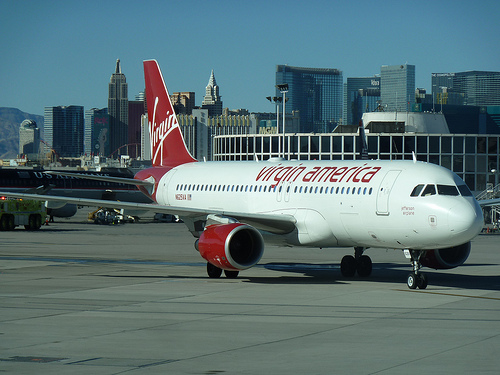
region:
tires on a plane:
[404, 266, 434, 293]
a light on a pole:
[273, 74, 303, 134]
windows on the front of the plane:
[413, 181, 446, 198]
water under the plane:
[271, 250, 317, 275]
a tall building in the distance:
[200, 65, 226, 116]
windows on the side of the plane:
[176, 175, 229, 193]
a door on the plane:
[375, 162, 397, 222]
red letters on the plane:
[258, 157, 309, 187]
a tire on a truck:
[23, 207, 48, 232]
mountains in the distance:
[3, 100, 26, 131]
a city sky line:
[17, 60, 490, 167]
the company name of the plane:
[249, 160, 379, 190]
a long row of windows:
[168, 181, 372, 205]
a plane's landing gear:
[334, 250, 377, 280]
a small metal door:
[375, 167, 398, 217]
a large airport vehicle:
[3, 195, 49, 232]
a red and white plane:
[18, 59, 485, 293]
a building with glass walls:
[209, 128, 491, 194]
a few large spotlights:
[261, 83, 293, 135]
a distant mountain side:
[0, 98, 55, 160]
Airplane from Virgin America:
[4, 55, 489, 305]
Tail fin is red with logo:
[116, 37, 200, 210]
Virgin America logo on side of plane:
[244, 150, 389, 195]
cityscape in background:
[1, 53, 495, 193]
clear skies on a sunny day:
[5, 3, 497, 103]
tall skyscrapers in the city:
[2, 47, 493, 148]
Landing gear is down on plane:
[190, 210, 455, 310]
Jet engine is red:
[192, 212, 265, 285]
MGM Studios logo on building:
[243, 110, 293, 150]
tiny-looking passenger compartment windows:
[172, 174, 379, 202]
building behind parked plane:
[108, 58, 128, 165]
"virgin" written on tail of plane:
[145, 96, 179, 163]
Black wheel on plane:
[206, 258, 223, 278]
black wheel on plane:
[340, 255, 359, 278]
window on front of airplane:
[410, 183, 424, 195]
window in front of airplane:
[434, 181, 459, 197]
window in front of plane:
[421, 182, 436, 195]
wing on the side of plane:
[2, 190, 298, 235]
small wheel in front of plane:
[405, 274, 416, 288]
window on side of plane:
[295, 186, 297, 194]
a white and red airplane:
[26, 61, 481, 296]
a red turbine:
[196, 226, 260, 274]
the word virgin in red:
[258, 160, 303, 185]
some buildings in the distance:
[47, 67, 131, 154]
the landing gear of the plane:
[208, 261, 426, 291]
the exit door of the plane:
[376, 168, 398, 217]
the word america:
[306, 166, 376, 182]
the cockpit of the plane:
[415, 183, 468, 195]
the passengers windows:
[178, 184, 374, 193]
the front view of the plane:
[407, 159, 483, 251]